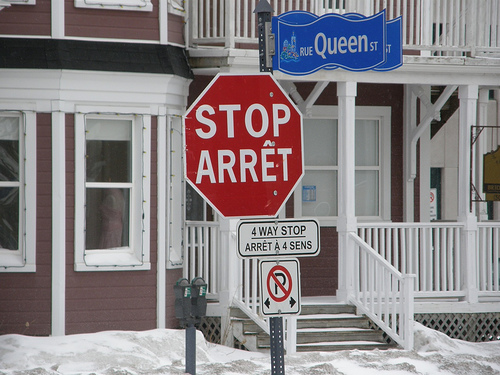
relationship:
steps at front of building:
[255, 309, 435, 353] [9, 20, 500, 332]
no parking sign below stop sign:
[249, 261, 319, 334] [184, 79, 317, 224]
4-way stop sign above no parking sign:
[243, 220, 335, 258] [249, 261, 319, 334]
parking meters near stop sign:
[180, 278, 221, 317] [184, 79, 317, 224]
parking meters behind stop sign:
[180, 278, 221, 317] [184, 79, 317, 224]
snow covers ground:
[31, 313, 450, 359] [16, 334, 181, 373]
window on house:
[69, 118, 151, 272] [9, 20, 500, 332]